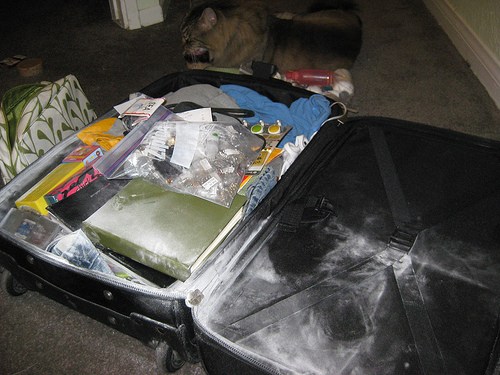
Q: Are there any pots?
A: No, there are no pots.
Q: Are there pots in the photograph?
A: No, there are no pots.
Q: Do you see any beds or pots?
A: No, there are no pots or beds.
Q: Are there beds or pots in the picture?
A: No, there are no pots or beds.